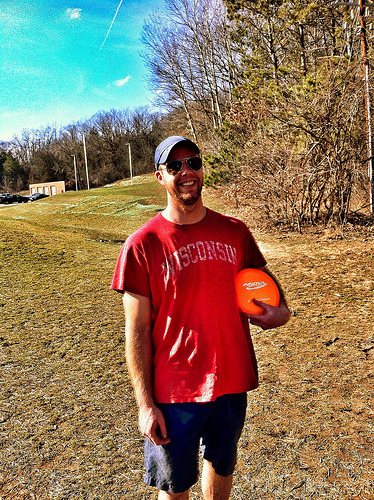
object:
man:
[109, 134, 291, 499]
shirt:
[109, 204, 268, 404]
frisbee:
[234, 267, 281, 316]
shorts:
[142, 390, 249, 495]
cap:
[152, 133, 201, 171]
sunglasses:
[154, 156, 206, 176]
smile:
[176, 178, 199, 191]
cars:
[30, 191, 49, 203]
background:
[0, 0, 374, 230]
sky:
[0, 0, 374, 156]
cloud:
[112, 73, 131, 89]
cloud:
[66, 5, 83, 22]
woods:
[138, 0, 239, 162]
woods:
[0, 105, 167, 190]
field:
[0, 170, 374, 499]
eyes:
[169, 162, 181, 171]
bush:
[270, 56, 374, 223]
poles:
[129, 143, 134, 185]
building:
[28, 179, 66, 199]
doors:
[50, 186, 56, 197]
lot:
[0, 192, 49, 206]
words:
[242, 280, 267, 290]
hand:
[239, 297, 283, 331]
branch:
[285, 474, 308, 494]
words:
[161, 239, 238, 291]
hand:
[136, 402, 172, 447]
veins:
[142, 405, 153, 433]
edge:
[142, 456, 237, 494]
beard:
[171, 176, 203, 206]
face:
[161, 146, 203, 204]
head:
[154, 135, 204, 206]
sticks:
[321, 337, 339, 346]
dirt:
[0, 167, 374, 500]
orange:
[262, 286, 276, 298]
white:
[243, 281, 267, 291]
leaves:
[244, 4, 251, 10]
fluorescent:
[243, 280, 268, 290]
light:
[125, 142, 129, 146]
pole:
[73, 154, 78, 190]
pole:
[82, 132, 90, 190]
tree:
[140, 4, 210, 176]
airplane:
[98, 46, 104, 53]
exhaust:
[101, 0, 124, 49]